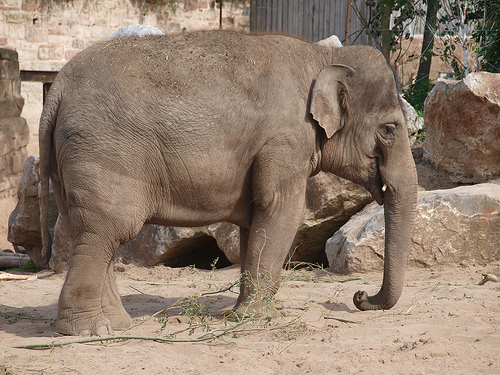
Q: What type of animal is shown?
A: Elephant.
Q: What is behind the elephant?
A: Rocks.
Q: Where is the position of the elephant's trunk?
A: Curled on the ground.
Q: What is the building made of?
A: Rock.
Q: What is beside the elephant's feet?
A: Tree branch.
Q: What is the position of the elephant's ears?
A: Laid back.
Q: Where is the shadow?
A: Behind the elephant.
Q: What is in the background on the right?
A: Tree.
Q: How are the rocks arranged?
A: Stacked.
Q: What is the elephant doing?
A: Standing.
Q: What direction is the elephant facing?
A: To the right.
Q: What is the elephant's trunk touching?
A: The ground.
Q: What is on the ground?
A: Sand.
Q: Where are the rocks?
A: Behind the elephant.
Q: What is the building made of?
A: Bricks.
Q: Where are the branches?
A: On the ground.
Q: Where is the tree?
A: Behind the rocks.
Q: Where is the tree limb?
A: On the ground.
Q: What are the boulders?
A: Behind the elephant.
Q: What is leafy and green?
A: Tree.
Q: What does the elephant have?
A: Tail.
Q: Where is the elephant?
A: In front of the boulders.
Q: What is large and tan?
A: Rocks.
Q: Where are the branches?
A: On the ground.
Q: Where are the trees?
A: In the back.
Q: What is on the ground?
A: Sand.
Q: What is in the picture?
A: An animal.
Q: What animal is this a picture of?
A: An elephant.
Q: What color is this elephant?
A: Brown.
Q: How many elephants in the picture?
A: One elephant.